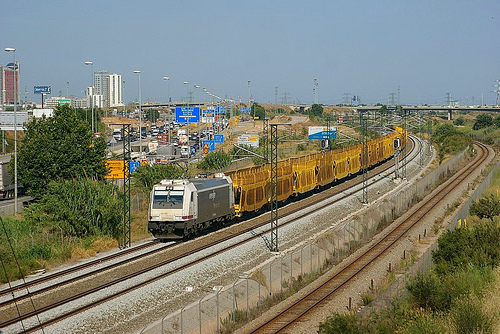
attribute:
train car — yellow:
[220, 157, 298, 217]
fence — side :
[62, 143, 334, 201]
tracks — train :
[55, 213, 460, 318]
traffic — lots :
[143, 137, 198, 162]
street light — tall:
[3, 45, 18, 55]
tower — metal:
[260, 115, 301, 255]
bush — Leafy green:
[405, 188, 498, 331]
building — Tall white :
[65, 41, 150, 115]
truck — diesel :
[157, 141, 180, 160]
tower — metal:
[117, 119, 137, 251]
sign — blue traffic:
[172, 105, 211, 132]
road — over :
[126, 109, 240, 155]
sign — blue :
[179, 104, 201, 119]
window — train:
[151, 194, 184, 206]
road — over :
[114, 98, 246, 183]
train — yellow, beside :
[146, 118, 405, 240]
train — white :
[110, 82, 432, 274]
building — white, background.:
[89, 70, 127, 112]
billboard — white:
[299, 112, 348, 142]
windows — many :
[109, 193, 179, 334]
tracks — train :
[8, 235, 189, 329]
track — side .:
[13, 240, 253, 331]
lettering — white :
[128, 164, 143, 179]